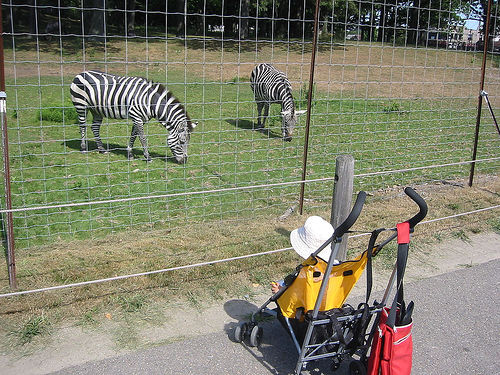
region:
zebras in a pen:
[63, 58, 308, 165]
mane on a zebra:
[150, 80, 197, 132]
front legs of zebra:
[122, 115, 153, 162]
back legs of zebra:
[68, 110, 108, 156]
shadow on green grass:
[220, 111, 270, 134]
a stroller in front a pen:
[151, 75, 443, 372]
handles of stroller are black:
[333, 170, 435, 246]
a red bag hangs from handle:
[367, 210, 424, 373]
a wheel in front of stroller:
[228, 310, 274, 357]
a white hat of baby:
[254, 212, 346, 316]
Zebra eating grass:
[63, 68, 191, 166]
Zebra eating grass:
[243, 60, 300, 148]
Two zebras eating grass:
[60, 48, 302, 162]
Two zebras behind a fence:
[60, 53, 312, 156]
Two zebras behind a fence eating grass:
[60, 52, 305, 167]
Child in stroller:
[234, 154, 441, 373]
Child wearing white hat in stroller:
[231, 184, 426, 374]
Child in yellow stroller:
[240, 185, 425, 374]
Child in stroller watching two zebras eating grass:
[52, 46, 437, 373]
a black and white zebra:
[69, 63, 196, 167]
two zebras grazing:
[64, 57, 307, 166]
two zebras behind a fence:
[1, 2, 498, 264]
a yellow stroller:
[232, 185, 432, 373]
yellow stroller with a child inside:
[226, 188, 435, 371]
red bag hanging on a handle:
[373, 220, 425, 373]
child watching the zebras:
[235, 215, 341, 357]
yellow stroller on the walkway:
[222, 185, 493, 374]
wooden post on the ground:
[328, 152, 358, 268]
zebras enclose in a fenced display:
[1, 2, 498, 300]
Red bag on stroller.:
[365, 222, 429, 372]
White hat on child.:
[288, 214, 339, 273]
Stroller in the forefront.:
[243, 182, 435, 374]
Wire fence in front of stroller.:
[2, 1, 497, 288]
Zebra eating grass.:
[65, 61, 194, 174]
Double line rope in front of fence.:
[0, 145, 498, 310]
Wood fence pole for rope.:
[327, 151, 354, 258]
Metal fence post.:
[295, 0, 332, 215]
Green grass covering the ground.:
[7, 70, 497, 246]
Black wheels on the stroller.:
[232, 320, 264, 348]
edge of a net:
[108, 227, 127, 246]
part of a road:
[442, 297, 453, 317]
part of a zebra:
[116, 101, 131, 115]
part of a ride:
[301, 268, 307, 283]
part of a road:
[445, 291, 452, 316]